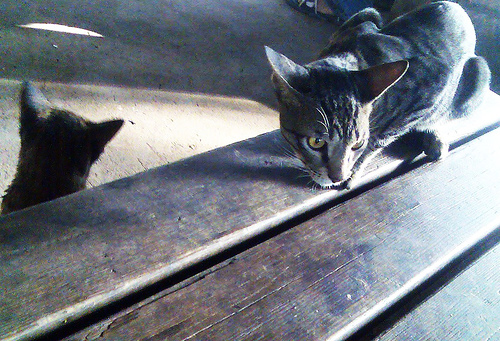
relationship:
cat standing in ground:
[16, 85, 138, 224] [27, 98, 499, 332]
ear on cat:
[356, 60, 411, 104] [257, 2, 492, 189]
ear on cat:
[262, 44, 309, 106] [257, 2, 492, 189]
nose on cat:
[323, 146, 350, 187] [267, 5, 499, 194]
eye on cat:
[306, 136, 325, 150] [267, 5, 499, 194]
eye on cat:
[347, 140, 364, 152] [267, 5, 499, 194]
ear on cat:
[262, 44, 309, 106] [267, 5, 499, 194]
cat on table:
[267, 5, 499, 194] [1, 89, 498, 339]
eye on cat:
[350, 134, 366, 151] [267, 5, 499, 194]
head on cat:
[267, 40, 410, 189] [267, 5, 499, 194]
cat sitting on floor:
[0, 81, 126, 218] [0, 0, 499, 214]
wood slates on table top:
[0, 83, 499, 337] [2, 87, 497, 339]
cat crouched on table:
[262, 0, 490, 191] [1, 89, 498, 339]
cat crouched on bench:
[267, 5, 499, 194] [5, 68, 498, 335]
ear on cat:
[364, 53, 415, 114] [257, 2, 492, 189]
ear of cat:
[17, 80, 55, 133] [0, 81, 126, 218]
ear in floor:
[17, 80, 55, 133] [2, 0, 498, 214]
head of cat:
[243, 36, 428, 200] [257, 2, 492, 189]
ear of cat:
[355, 60, 410, 107] [255, 32, 474, 211]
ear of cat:
[262, 44, 309, 106] [257, 2, 492, 189]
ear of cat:
[91, 116, 123, 151] [0, 81, 126, 218]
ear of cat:
[10, 82, 79, 134] [15, 75, 120, 235]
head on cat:
[15, 80, 124, 167] [257, 2, 492, 189]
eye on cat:
[308, 135, 325, 150] [257, 2, 492, 189]